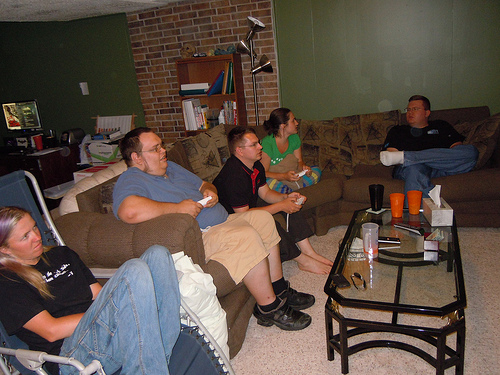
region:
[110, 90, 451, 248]
people on a couch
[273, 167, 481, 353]
table in front of people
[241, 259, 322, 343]
shoes on man's feet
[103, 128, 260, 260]
man in blue shirt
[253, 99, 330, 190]
girl sitting on couch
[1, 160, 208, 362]
woman in a chair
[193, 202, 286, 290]
Shorts on a person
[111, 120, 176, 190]
The man has glasses on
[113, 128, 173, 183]
The man has eyeglasses on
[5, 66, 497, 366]
A room full of people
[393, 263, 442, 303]
Glass surface on a table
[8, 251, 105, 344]
Black shirt on a woman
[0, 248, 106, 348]
Shirt on a woman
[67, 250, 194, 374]
Pants on a woman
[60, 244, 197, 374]
Blue jeans on a woman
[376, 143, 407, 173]
Sock on a man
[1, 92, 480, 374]
people sitting in living room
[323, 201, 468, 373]
glass topped coffee table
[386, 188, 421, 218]
two orange glasses on coffee table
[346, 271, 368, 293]
sunglasses on coffee table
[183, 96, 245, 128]
books on a shelf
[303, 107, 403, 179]
pillowa on a couch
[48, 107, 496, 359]
brown sectional sofa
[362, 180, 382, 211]
dark glass on light paper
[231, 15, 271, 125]
silver floor lamp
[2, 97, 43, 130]
computer monitor0n desk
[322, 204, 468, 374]
A black framed coffee table with glass.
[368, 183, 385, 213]
A black plastic cup on the edge of a coffee table.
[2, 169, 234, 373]
A white framed chair with blue fabric.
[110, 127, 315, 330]
A large man in tan shorts and blue shirt.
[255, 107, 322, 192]
Dark haired girl in green shirt.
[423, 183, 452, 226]
Light brown box of tissues.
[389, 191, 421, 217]
Two orange cups on a table.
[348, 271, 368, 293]
Black and silver sunglasses on a table.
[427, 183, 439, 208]
White tissue coming out of a box.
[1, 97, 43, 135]
Computer screen that is turned on.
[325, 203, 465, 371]
a wood and glass coffee table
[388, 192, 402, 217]
a solid orange cup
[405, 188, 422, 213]
a solid orange cup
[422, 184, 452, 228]
a box of facial tissue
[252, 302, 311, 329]
a man's black shoe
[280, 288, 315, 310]
a man's black shoe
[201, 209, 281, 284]
a tan pair of shorts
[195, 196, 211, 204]
a Wii game controller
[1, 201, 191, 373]
Woman with blonde hair sitting in a folding chair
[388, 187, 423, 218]
Two orange cups on the coffee table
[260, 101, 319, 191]
Woman in green shirt sitting cross-legged on the sofa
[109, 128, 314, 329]
Heavy-set man wearing blue t-shirt and tan shorts